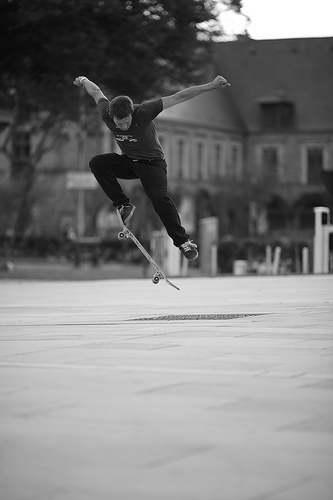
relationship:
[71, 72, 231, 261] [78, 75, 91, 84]
boy wearing watch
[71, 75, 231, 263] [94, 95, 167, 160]
boy wearing t-shirt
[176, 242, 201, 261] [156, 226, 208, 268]
tennis shoe on man's foot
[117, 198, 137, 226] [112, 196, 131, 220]
tennis shoe on man's foot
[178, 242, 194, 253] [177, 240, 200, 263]
laces in tennis shoe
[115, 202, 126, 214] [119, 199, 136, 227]
laces in tennis shoe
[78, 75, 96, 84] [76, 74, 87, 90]
watch on wrist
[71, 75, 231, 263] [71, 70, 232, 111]
boy has arm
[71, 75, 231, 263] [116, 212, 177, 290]
boy jumping skateboard